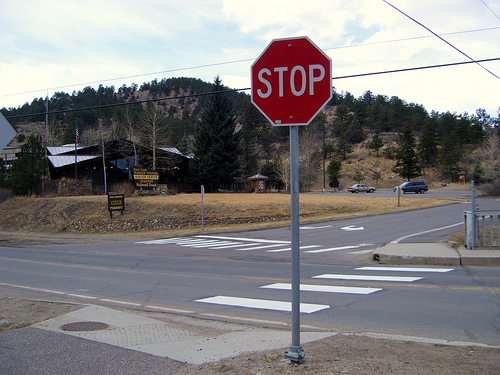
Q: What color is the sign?
A: Red.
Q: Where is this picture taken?
A: A street.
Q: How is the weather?
A: Clear.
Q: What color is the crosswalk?
A: White.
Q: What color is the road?
A: Gray.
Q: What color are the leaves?
A: Green.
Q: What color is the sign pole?
A: Gray.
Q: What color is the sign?
A: Red.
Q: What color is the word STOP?
A: White.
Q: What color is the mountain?
A: Brown.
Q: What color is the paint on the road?
A: White.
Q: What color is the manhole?
A: Gray.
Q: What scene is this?
A: Street corner.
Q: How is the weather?
A: Fair.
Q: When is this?
A: Afternoon.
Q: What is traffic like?
A: Empty.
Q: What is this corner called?
A: Intersection.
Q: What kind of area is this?
A: Rural.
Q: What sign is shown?
A: Stop sign.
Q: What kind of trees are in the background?
A: Pine.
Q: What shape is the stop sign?
A: An octagon.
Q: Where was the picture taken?
A: An intersection.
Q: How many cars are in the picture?
A: Two.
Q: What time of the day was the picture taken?
A: Daytime.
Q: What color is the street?
A: Gray.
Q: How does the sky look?
A: Cloudy.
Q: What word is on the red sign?
A: Stop.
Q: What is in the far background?
A: A hill.